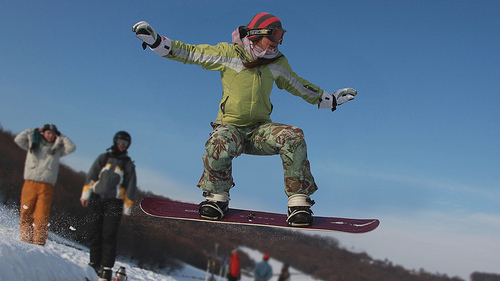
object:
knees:
[202, 122, 304, 163]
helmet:
[240, 12, 286, 52]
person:
[132, 12, 380, 235]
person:
[137, 12, 377, 233]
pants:
[193, 118, 313, 198]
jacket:
[165, 39, 333, 134]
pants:
[78, 187, 132, 272]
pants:
[20, 172, 50, 251]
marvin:
[241, 12, 286, 43]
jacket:
[13, 129, 74, 184]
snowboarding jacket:
[152, 33, 338, 126]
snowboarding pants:
[17, 179, 53, 245]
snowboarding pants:
[82, 189, 123, 272]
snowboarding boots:
[193, 189, 231, 218]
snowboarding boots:
[281, 199, 316, 226]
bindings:
[196, 199, 225, 214]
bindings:
[283, 207, 312, 221]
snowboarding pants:
[197, 117, 318, 204]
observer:
[12, 124, 74, 247]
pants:
[17, 178, 48, 248]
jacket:
[13, 125, 78, 183]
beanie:
[244, 10, 285, 35]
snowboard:
[137, 197, 380, 232]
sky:
[0, 0, 498, 280]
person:
[79, 130, 137, 279]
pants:
[195, 121, 317, 197]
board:
[135, 197, 380, 232]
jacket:
[162, 24, 334, 127]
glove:
[126, 20, 157, 48]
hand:
[130, 19, 158, 49]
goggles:
[244, 30, 282, 42]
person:
[11, 123, 74, 245]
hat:
[249, 13, 281, 36]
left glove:
[318, 86, 358, 112]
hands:
[316, 87, 355, 111]